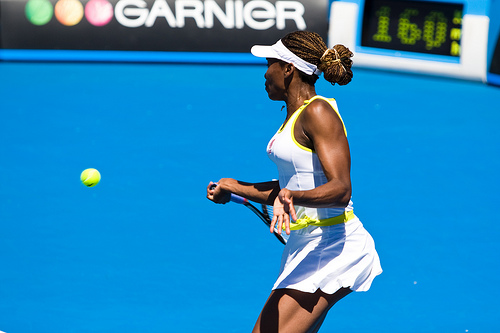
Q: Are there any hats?
A: Yes, there is a hat.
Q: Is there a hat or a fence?
A: Yes, there is a hat.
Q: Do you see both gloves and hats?
A: No, there is a hat but no gloves.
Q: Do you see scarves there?
A: No, there are no scarves.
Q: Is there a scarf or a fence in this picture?
A: No, there are no scarves or fences.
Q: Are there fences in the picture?
A: No, there are no fences.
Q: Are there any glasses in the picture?
A: No, there are no glasses.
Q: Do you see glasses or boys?
A: No, there are no glasses or boys.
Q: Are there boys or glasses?
A: No, there are no glasses or boys.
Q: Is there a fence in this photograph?
A: No, there are no fences.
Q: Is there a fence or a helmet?
A: No, there are no fences or helmets.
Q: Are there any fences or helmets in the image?
A: No, there are no fences or helmets.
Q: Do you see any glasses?
A: No, there are no glasses.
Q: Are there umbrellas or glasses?
A: No, there are no glasses or umbrellas.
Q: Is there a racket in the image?
A: Yes, there is a racket.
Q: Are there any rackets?
A: Yes, there is a racket.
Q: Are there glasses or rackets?
A: Yes, there is a racket.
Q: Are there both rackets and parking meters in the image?
A: No, there is a racket but no parking meters.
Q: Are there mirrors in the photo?
A: No, there are no mirrors.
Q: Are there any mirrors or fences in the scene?
A: No, there are no mirrors or fences.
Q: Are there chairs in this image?
A: No, there are no chairs.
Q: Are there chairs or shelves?
A: No, there are no chairs or shelves.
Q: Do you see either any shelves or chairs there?
A: No, there are no chairs or shelves.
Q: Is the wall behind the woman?
A: Yes, the wall is behind the woman.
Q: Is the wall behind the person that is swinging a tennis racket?
A: Yes, the wall is behind the woman.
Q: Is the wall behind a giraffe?
A: No, the wall is behind the woman.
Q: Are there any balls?
A: Yes, there is a ball.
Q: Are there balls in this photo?
A: Yes, there is a ball.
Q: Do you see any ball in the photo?
A: Yes, there is a ball.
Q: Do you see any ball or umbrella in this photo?
A: Yes, there is a ball.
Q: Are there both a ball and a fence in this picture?
A: No, there is a ball but no fences.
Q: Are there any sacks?
A: No, there are no sacks.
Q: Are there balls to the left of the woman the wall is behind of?
A: Yes, there is a ball to the left of the woman.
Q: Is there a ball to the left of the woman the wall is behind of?
A: Yes, there is a ball to the left of the woman.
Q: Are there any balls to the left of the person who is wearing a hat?
A: Yes, there is a ball to the left of the woman.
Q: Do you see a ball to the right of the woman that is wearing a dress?
A: No, the ball is to the left of the woman.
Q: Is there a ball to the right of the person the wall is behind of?
A: No, the ball is to the left of the woman.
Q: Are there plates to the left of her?
A: No, there is a ball to the left of the woman.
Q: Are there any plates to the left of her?
A: No, there is a ball to the left of the woman.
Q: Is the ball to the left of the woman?
A: Yes, the ball is to the left of the woman.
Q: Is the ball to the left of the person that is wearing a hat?
A: Yes, the ball is to the left of the woman.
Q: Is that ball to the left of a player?
A: No, the ball is to the left of the woman.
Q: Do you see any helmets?
A: No, there are no helmets.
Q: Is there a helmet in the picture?
A: No, there are no helmets.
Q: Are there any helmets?
A: No, there are no helmets.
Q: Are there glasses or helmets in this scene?
A: No, there are no helmets or glasses.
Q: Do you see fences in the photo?
A: No, there are no fences.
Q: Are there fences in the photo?
A: No, there are no fences.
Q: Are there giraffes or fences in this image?
A: No, there are no fences or giraffes.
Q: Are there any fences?
A: No, there are no fences.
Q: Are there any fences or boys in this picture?
A: No, there are no fences or boys.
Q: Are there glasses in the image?
A: No, there are no glasses.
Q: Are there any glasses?
A: No, there are no glasses.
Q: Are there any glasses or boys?
A: No, there are no glasses or boys.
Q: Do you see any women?
A: Yes, there is a woman.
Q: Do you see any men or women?
A: Yes, there is a woman.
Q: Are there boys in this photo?
A: No, there are no boys.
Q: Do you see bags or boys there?
A: No, there are no boys or bags.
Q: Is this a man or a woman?
A: This is a woman.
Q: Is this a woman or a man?
A: This is a woman.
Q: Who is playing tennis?
A: The woman is playing tennis.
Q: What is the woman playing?
A: The woman is playing tennis.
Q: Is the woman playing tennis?
A: Yes, the woman is playing tennis.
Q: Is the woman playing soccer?
A: No, the woman is playing tennis.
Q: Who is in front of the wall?
A: The woman is in front of the wall.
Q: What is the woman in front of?
A: The woman is in front of the wall.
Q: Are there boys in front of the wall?
A: No, there is a woman in front of the wall.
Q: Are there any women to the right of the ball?
A: Yes, there is a woman to the right of the ball.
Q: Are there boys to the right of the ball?
A: No, there is a woman to the right of the ball.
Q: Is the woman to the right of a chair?
A: No, the woman is to the right of the ball.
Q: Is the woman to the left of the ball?
A: No, the woman is to the right of the ball.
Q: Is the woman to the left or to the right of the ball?
A: The woman is to the right of the ball.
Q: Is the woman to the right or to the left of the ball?
A: The woman is to the right of the ball.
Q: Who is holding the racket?
A: The woman is holding the racket.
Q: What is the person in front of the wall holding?
A: The woman is holding the tennis racket.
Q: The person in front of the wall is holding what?
A: The woman is holding the tennis racket.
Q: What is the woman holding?
A: The woman is holding the tennis racket.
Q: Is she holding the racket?
A: Yes, the woman is holding the racket.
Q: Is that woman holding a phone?
A: No, the woman is holding the racket.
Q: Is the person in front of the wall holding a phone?
A: No, the woman is holding the racket.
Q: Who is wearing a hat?
A: The woman is wearing a hat.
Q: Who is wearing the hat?
A: The woman is wearing a hat.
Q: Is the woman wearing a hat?
A: Yes, the woman is wearing a hat.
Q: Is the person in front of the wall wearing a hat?
A: Yes, the woman is wearing a hat.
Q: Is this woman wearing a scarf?
A: No, the woman is wearing a hat.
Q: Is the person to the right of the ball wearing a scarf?
A: No, the woman is wearing a hat.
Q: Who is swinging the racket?
A: The woman is swinging the racket.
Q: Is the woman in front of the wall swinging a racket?
A: Yes, the woman is swinging a racket.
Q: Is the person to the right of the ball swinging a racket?
A: Yes, the woman is swinging a racket.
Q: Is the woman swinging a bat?
A: No, the woman is swinging a racket.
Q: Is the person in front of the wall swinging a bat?
A: No, the woman is swinging a racket.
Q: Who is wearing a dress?
A: The woman is wearing a dress.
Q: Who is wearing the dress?
A: The woman is wearing a dress.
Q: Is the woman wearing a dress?
A: Yes, the woman is wearing a dress.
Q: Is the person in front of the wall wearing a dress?
A: Yes, the woman is wearing a dress.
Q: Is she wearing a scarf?
A: No, the woman is wearing a dress.